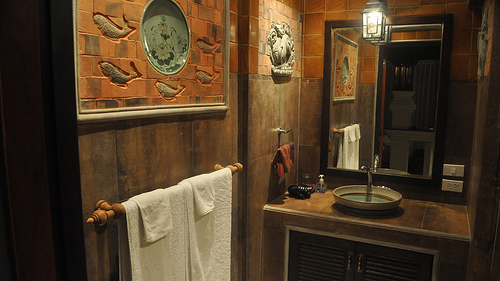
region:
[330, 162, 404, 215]
A bowl designed sink.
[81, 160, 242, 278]
White towels and wash cloths on a rack.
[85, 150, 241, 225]
A brown wooden towel rack.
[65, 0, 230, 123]
A picture hanging above the towel rack.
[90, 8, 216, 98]
Images of whales on the picture.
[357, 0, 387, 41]
A light fixture with a black base.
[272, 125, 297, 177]
A red wash cloth hanging on a small rack.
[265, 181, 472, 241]
A brown marble countertop.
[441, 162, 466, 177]
White light switch next to a the mirror.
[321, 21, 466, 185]
A framed mirror behind the sink.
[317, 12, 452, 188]
black bordered mirror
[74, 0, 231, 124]
decorative area on wall with whales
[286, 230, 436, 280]
black under the sing cupboard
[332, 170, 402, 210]
bowl shaped sink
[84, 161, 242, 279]
white towels hanging on rod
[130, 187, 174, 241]
white washcloth hanging on towel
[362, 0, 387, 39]
light on bathroom ceiling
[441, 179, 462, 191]
electrical outlets near the sink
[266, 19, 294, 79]
stone carving on wall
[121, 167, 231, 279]
white washcloths and towls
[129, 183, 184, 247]
wash cloth on the towel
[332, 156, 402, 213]
sink bowl with faucet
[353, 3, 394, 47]
light on the ceiling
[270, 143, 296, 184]
washcloth on the bar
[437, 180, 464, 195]
outlets on the wall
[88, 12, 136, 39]
fish on the plaque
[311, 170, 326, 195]
soap on the sink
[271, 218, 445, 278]
drawers built into the wall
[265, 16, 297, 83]
statue on the wall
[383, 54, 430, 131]
window in the mirror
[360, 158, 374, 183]
The faucet of the sink.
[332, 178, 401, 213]
The basin of the sink.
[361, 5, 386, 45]
The light near the mirror.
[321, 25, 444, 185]
The mirror in the bathroom.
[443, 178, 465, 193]
The electrical socket next to the mirror.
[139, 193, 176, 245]
The wash cloth on the bar on the left.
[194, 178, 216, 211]
The wash cloth on the right.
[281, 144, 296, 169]
The colorful wash cloths next to the sink area.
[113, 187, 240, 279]
The large towels hanging up.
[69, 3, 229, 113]
The frame above the white towels.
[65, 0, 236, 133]
art with whales on it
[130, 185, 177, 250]
white hand towel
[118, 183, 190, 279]
white hand towel folded over a bath towel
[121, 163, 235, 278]
two white hand towels folded over two bath towels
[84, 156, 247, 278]
wooden towel rack with two hand towels and two bath towels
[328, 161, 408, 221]
modern bowl sink and faucet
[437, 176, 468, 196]
horizontal white electrical outlets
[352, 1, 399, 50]
modern light fixture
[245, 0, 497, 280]
very modern bathroom sink area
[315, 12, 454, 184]
mirror with a reflection of a bathroom in it